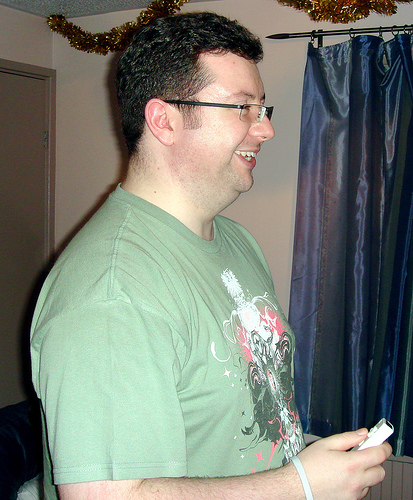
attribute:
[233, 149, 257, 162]
teeth — White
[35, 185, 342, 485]
shirt — design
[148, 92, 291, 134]
black glasses — thin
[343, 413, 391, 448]
remote — white, black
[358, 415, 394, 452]
controller — white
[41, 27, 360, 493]
man — playing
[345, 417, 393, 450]
controller — white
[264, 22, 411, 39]
curtain rod — black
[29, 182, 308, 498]
shirt — green, short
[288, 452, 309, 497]
strap — grey